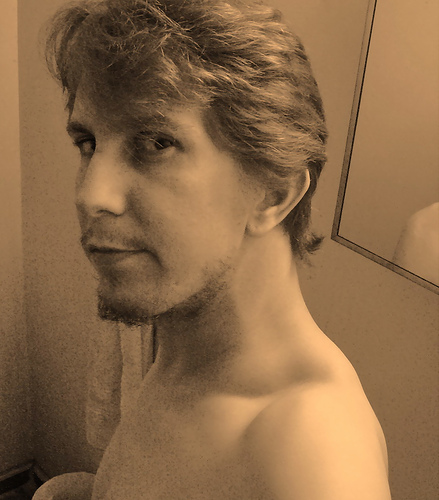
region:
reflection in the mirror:
[375, 204, 432, 291]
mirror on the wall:
[264, 2, 435, 339]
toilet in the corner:
[32, 461, 96, 498]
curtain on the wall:
[61, 310, 154, 460]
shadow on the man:
[184, 364, 335, 431]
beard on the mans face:
[91, 243, 243, 349]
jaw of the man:
[88, 231, 245, 345]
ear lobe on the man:
[246, 220, 272, 256]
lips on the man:
[81, 239, 143, 269]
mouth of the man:
[74, 237, 165, 274]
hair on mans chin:
[89, 288, 141, 322]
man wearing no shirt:
[126, 396, 225, 482]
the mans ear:
[251, 164, 315, 232]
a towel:
[87, 347, 134, 385]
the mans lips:
[85, 240, 129, 266]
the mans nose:
[75, 177, 120, 214]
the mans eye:
[131, 132, 178, 158]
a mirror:
[340, 169, 390, 250]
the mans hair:
[218, 99, 297, 151]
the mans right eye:
[75, 139, 95, 153]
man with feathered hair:
[37, 0, 346, 326]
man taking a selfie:
[19, 5, 404, 495]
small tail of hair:
[280, 199, 329, 281]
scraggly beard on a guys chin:
[87, 266, 232, 332]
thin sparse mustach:
[72, 220, 149, 255]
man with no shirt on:
[39, 4, 402, 498]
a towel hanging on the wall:
[81, 289, 162, 461]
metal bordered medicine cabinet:
[333, 4, 434, 301]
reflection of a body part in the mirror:
[393, 188, 438, 287]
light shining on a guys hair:
[144, 3, 276, 112]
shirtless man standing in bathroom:
[43, 14, 390, 490]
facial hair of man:
[82, 221, 221, 330]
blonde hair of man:
[32, 0, 338, 243]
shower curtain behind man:
[64, 300, 149, 431]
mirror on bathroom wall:
[326, 69, 437, 261]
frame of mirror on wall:
[318, 1, 437, 307]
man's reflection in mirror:
[381, 190, 433, 287]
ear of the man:
[231, 146, 308, 230]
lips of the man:
[76, 238, 139, 270]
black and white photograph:
[13, 10, 421, 484]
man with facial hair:
[73, 225, 225, 329]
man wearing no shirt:
[74, 336, 437, 495]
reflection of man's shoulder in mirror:
[395, 207, 437, 283]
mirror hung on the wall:
[330, 30, 412, 312]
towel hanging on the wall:
[69, 309, 146, 448]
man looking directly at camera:
[43, 5, 323, 326]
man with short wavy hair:
[83, 17, 320, 118]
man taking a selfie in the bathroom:
[27, 1, 392, 484]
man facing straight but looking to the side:
[28, 0, 334, 333]